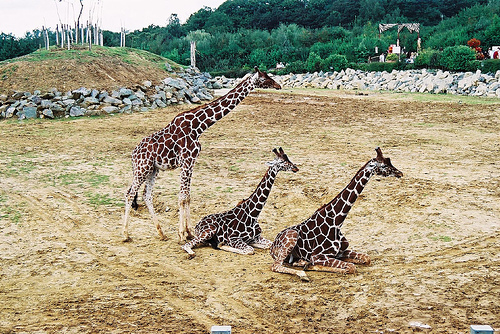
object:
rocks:
[5, 70, 220, 120]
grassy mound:
[0, 43, 204, 104]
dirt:
[272, 283, 433, 325]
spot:
[179, 119, 193, 136]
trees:
[247, 22, 343, 69]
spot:
[315, 221, 330, 238]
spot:
[312, 231, 326, 247]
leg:
[319, 257, 357, 273]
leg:
[345, 250, 370, 263]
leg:
[276, 245, 299, 275]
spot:
[205, 117, 214, 124]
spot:
[248, 207, 262, 218]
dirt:
[245, 88, 439, 123]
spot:
[324, 207, 333, 214]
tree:
[438, 43, 477, 70]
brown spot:
[342, 189, 350, 201]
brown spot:
[237, 209, 245, 221]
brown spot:
[180, 120, 192, 135]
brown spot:
[309, 239, 317, 250]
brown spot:
[205, 218, 212, 223]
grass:
[63, 164, 122, 208]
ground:
[2, 95, 494, 331]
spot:
[254, 186, 266, 196]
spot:
[294, 226, 320, 253]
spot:
[160, 137, 177, 150]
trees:
[40, 0, 127, 47]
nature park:
[0, 2, 497, 334]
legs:
[179, 147, 194, 225]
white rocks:
[345, 71, 458, 93]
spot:
[248, 195, 262, 206]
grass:
[0, 147, 39, 177]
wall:
[213, 67, 498, 99]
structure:
[374, 16, 424, 65]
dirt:
[0, 277, 153, 315]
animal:
[123, 66, 282, 243]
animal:
[181, 147, 299, 261]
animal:
[268, 145, 404, 283]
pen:
[1, 31, 484, 331]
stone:
[208, 66, 495, 98]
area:
[0, 42, 500, 332]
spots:
[135, 141, 165, 159]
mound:
[1, 41, 210, 118]